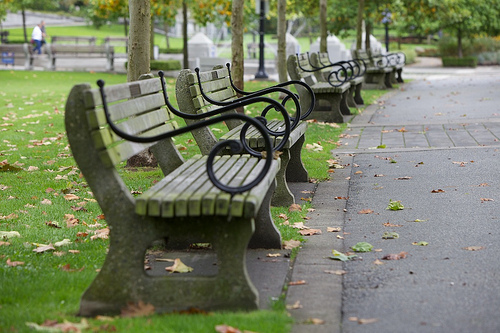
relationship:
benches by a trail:
[63, 35, 434, 307] [287, 42, 499, 331]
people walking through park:
[16, 13, 76, 58] [45, 51, 416, 273]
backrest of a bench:
[52, 68, 189, 206] [62, 75, 284, 318]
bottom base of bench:
[77, 210, 259, 312] [62, 75, 284, 318]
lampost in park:
[380, 10, 392, 51] [2, 69, 498, 321]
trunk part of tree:
[127, 8, 160, 158] [204, 1, 261, 108]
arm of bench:
[94, 81, 272, 193] [76, 76, 288, 283]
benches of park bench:
[63, 71, 292, 314] [353, 42, 397, 85]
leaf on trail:
[382, 193, 410, 217] [292, 67, 499, 331]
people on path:
[32, 23, 44, 54] [6, 45, 127, 69]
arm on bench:
[94, 81, 272, 193] [62, 75, 284, 318]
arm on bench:
[94, 81, 272, 193] [365, 32, 406, 84]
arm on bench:
[94, 81, 272, 193] [287, 52, 360, 123]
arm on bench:
[94, 81, 272, 193] [176, 63, 329, 207]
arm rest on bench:
[362, 53, 390, 68] [62, 75, 284, 318]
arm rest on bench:
[297, 54, 347, 85] [176, 65, 312, 205]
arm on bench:
[94, 81, 272, 193] [283, 52, 349, 125]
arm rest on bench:
[182, 66, 291, 151] [353, 48, 392, 87]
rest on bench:
[95, 95, 277, 199] [62, 75, 284, 318]